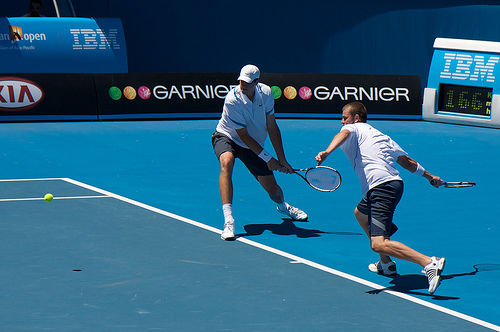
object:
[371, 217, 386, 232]
stripe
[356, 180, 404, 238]
shorts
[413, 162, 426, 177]
band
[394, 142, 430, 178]
arm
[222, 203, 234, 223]
socks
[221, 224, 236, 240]
sneakers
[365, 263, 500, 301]
shadow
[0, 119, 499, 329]
court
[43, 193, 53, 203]
tennis ball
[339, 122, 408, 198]
shirt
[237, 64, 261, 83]
hat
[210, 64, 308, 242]
man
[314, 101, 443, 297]
man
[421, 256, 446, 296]
shoe